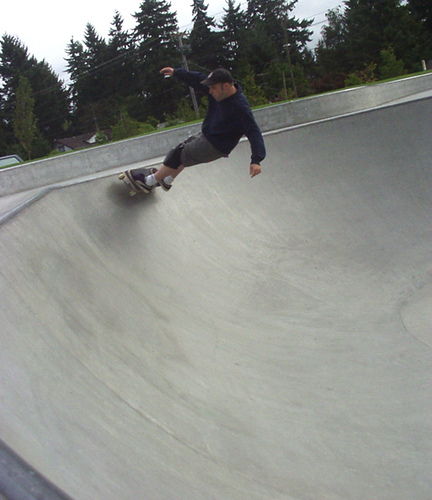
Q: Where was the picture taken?
A: Skatepark.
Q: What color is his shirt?
A: Blue.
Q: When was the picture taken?
A: Daytime.